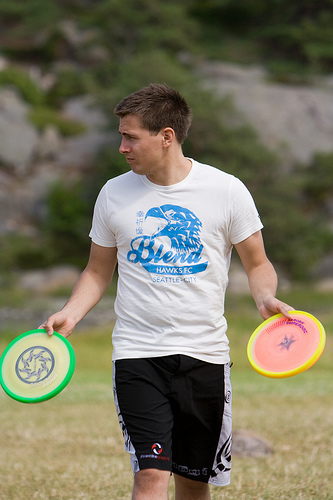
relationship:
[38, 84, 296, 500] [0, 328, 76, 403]
man walking with frisbee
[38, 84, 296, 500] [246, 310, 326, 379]
man walking with frisbee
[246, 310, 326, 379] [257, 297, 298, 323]
frisbee in hand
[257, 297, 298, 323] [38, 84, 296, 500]
hand of man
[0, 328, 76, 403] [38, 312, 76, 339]
frisbee in hand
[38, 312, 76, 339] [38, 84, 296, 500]
hand of man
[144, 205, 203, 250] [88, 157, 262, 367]
hawk on shirt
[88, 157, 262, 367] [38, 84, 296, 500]
shirt of man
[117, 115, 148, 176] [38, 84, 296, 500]
face of man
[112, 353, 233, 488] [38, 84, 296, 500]
shorts on man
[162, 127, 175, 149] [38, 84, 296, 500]
ear of man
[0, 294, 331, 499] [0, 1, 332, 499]
grass in park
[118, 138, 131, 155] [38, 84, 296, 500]
nose of man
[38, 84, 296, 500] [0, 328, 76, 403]
man holding frisbee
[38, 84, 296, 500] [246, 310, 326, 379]
man holding frisbee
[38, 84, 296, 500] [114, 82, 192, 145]
man with hair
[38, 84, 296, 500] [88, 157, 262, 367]
man wearing shirt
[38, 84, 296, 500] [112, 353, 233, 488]
man wearing shorts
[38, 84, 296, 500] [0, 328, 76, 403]
man holds frisbee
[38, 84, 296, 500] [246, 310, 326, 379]
man holds frisbee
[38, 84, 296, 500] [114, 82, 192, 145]
man has hair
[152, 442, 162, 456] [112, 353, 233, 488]
logo on shorts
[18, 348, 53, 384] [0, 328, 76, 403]
sun shape in middle of frisbee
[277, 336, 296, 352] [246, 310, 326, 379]
design on frisbee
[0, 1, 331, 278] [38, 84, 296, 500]
foliage behind man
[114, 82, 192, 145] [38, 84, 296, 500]
hair of man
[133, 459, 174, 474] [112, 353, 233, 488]
edge of shorts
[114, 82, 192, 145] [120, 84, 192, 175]
hair on head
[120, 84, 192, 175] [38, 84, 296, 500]
head of man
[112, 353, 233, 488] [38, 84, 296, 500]
shorts of man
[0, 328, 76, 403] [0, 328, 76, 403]
frisbee on frisbee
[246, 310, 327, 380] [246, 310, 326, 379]
trim on frisbee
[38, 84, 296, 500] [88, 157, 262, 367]
man wears shirt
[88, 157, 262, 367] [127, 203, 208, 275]
shirt with design